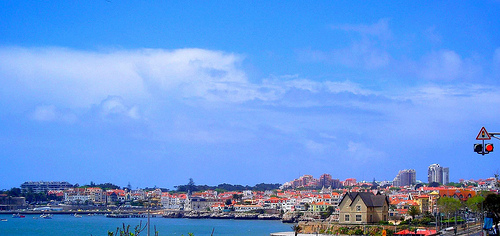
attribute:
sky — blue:
[0, 2, 495, 187]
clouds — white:
[1, 45, 498, 155]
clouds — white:
[55, 18, 250, 80]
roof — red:
[103, 187, 119, 194]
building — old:
[104, 187, 122, 204]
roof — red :
[314, 195, 327, 203]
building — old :
[309, 196, 331, 216]